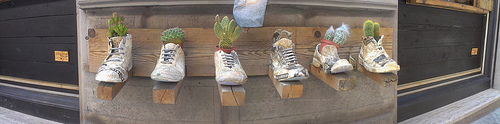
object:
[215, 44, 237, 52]
pot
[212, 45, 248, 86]
plant pots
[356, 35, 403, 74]
plant pots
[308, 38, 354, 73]
plant pots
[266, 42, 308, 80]
plant pots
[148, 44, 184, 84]
plant pots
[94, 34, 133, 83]
plant pots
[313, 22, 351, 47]
cactus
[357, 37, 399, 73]
shoe.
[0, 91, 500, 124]
ground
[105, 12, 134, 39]
cactus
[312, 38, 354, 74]
casual shoe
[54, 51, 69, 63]
plaque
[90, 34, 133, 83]
shoe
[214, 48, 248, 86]
shoe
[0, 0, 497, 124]
background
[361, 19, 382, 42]
catuses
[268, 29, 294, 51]
catuses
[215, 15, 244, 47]
catuses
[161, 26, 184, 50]
catuses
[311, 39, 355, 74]
shoe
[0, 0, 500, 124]
wall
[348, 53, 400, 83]
pot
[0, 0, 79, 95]
boards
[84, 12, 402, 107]
display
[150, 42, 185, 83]
shoe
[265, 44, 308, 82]
shoe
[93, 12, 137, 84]
pots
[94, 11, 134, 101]
cacti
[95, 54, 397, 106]
wood